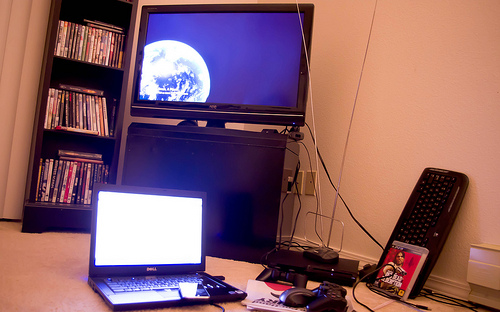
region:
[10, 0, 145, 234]
a movie shelf by the television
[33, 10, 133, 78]
a shelf movies lined in a row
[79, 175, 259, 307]
a laptop sitting in floor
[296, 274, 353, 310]
a play station controller by the mouse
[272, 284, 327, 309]
a computer mouse by the controller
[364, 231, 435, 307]
a video game case leaning on the keyboard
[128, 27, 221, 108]
a moon on the t.v. screen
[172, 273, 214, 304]
a cell phone on the laptop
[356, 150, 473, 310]
a keyboard propped up against the wall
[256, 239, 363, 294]
a play station sitting on the floor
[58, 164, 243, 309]
laptop on the floor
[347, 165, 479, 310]
black keyboard leaning on the wall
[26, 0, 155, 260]
DVDs on the shelf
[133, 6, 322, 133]
flat screen television on a stand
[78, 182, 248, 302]
laptop sitting on the carpet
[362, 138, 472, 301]
black keyboard against the wall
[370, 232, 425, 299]
video game leaning on keyboard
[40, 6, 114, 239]
black book case on wall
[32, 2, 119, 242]
DVD's in a black book case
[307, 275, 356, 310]
wireless video game controller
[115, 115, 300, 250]
black television stand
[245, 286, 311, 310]
silver remote control on the floor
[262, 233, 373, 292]
black video game system on the floor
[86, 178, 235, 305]
open black laptop sitting on floor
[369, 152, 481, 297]
black computer keyboard against white wall with red cd leaning against it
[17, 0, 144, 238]
black wooden shelve with three shelves and cds on each shelf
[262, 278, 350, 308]
black mouse and other remotes on floor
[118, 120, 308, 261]
black rectangular TV stand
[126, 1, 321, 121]
rectangular TV on platform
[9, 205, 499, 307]
off white carpet in living room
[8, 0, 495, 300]
off white walls in living room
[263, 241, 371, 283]
black movie and cd player on floor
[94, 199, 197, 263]
bright white lit screen of laptop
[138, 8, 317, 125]
black flat screen tv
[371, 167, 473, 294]
black computer key board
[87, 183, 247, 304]
black dell laptop computer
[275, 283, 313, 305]
black and grey mouse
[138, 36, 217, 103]
photo of moon on tv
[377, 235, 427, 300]
play station video game case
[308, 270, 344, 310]
black play station controller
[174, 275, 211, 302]
cell phone laying on laptop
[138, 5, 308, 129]
large size black tv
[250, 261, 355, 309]
two black video game controllers